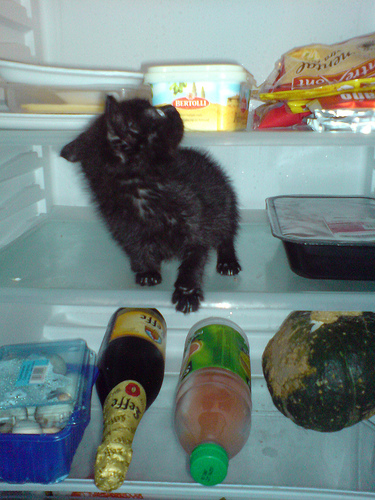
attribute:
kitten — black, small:
[63, 96, 241, 285]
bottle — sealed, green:
[98, 308, 164, 491]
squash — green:
[262, 307, 371, 431]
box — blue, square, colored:
[0, 339, 96, 484]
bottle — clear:
[182, 317, 252, 486]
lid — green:
[188, 441, 227, 485]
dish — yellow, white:
[146, 66, 253, 132]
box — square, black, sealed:
[266, 192, 373, 283]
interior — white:
[42, 4, 294, 62]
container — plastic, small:
[2, 64, 140, 119]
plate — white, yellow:
[2, 114, 108, 126]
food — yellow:
[14, 103, 115, 115]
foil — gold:
[95, 460, 129, 489]